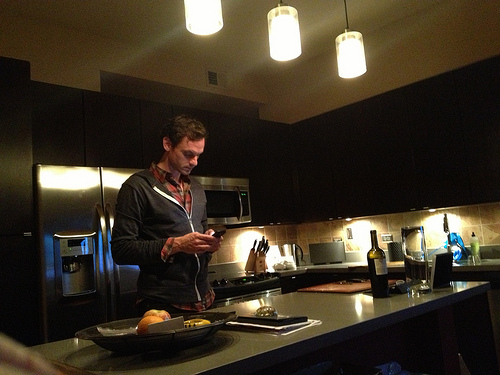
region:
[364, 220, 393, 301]
a large wine bottle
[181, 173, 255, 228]
part of a microwave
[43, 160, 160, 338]
part of a large refrigerator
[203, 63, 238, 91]
a white vent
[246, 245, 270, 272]
a wooden knife block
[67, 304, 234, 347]
a large bowl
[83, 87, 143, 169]
a brown cabinet door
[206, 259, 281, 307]
part of an oven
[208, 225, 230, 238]
part of a cellphone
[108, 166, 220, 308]
a man's black jacket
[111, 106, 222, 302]
man wearing a jacket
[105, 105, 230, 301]
man wearing a plaid shirt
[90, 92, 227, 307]
man holding a phone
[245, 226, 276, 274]
knives on a counter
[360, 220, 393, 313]
tall bottle of wine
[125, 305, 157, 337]
fruit in a bowl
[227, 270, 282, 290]
stove in a kitchen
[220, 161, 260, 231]
oven in a kitchen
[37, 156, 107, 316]
refrigerator in kitchen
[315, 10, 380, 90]
light in a ceiling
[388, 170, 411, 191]
part of a kitchen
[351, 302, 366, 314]
part of a counter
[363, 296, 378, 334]
edge of a counter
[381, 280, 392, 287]
part of a bottle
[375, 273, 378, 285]
edge of a bottle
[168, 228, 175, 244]
part of a sweater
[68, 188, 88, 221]
part of a fridge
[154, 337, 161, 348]
part of a tray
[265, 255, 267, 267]
part of a knife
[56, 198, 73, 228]
part of a reflection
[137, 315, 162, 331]
an orange in a bowl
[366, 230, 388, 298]
a bottle of wine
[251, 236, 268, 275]
knives in a knife block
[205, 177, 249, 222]
the front of an in wall microwave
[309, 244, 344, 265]
the front of a stainless steel toaster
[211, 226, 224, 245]
a small, black cell phone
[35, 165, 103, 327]
one door of a stainless steel refrigerator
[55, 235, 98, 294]
the ice and water dispenser on a refrigerator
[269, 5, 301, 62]
a modern light hanging from the ceiling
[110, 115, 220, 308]
a young man on his cell phone in the kitchen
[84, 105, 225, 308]
the man in the kitchen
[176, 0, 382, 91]
the lights on the ceiling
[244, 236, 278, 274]
the knives in the block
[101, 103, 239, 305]
the man on the cellphone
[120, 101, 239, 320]
the man wearing the plaid shirt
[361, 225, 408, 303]
the wine on the counter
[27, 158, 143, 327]
the refrigerator behind the man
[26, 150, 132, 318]
the refrigerator is metal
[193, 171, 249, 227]
the microwave above the range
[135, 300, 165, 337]
the fruit in the bowl